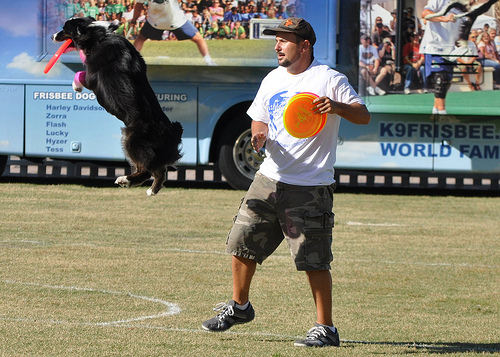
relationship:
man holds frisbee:
[196, 17, 372, 345] [284, 90, 326, 143]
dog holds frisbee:
[40, 17, 185, 202] [41, 39, 75, 76]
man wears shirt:
[196, 17, 372, 345] [248, 58, 361, 187]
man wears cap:
[196, 17, 372, 345] [259, 20, 318, 43]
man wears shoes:
[196, 17, 372, 345] [199, 296, 338, 347]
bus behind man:
[1, 2, 499, 194] [196, 17, 372, 345]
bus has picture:
[1, 2, 499, 194] [357, 2, 498, 110]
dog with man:
[40, 17, 185, 202] [196, 17, 372, 345]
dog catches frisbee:
[40, 17, 185, 202] [41, 39, 75, 76]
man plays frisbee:
[196, 17, 372, 345] [284, 90, 326, 143]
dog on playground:
[40, 17, 185, 202] [2, 185, 498, 357]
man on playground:
[196, 17, 372, 345] [2, 185, 498, 357]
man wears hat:
[196, 17, 372, 345] [259, 20, 318, 43]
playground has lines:
[2, 185, 498, 357] [19, 236, 183, 336]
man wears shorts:
[196, 17, 372, 345] [229, 170, 335, 268]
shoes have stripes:
[199, 296, 338, 347] [216, 310, 246, 326]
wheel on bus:
[212, 105, 267, 190] [1, 2, 499, 194]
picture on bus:
[357, 2, 498, 110] [1, 2, 499, 194]